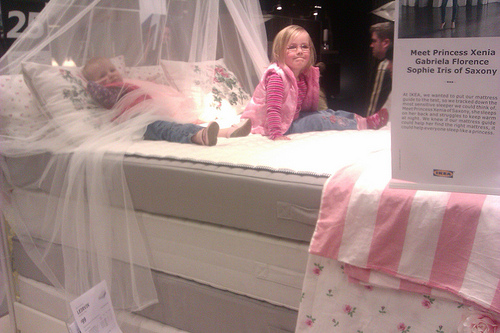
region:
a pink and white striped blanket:
[323, 168, 493, 303]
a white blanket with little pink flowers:
[300, 249, 420, 329]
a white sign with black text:
[383, 25, 497, 187]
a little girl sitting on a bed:
[250, 29, 385, 153]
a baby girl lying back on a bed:
[65, 39, 240, 155]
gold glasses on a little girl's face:
[281, 36, 313, 59]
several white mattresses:
[142, 174, 244, 306]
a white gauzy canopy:
[21, 13, 120, 274]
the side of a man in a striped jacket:
[354, 24, 393, 119]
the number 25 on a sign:
[5, 4, 45, 43]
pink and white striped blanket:
[322, 175, 495, 308]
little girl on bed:
[255, 28, 380, 135]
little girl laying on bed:
[83, 52, 243, 144]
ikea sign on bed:
[378, 4, 491, 191]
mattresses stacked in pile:
[169, 160, 242, 330]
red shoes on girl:
[363, 105, 386, 130]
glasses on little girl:
[281, 40, 311, 52]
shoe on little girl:
[197, 119, 222, 144]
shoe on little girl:
[224, 120, 256, 135]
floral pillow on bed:
[191, 52, 249, 113]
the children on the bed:
[81, 22, 388, 138]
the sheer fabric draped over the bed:
[8, 0, 265, 271]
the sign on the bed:
[392, 33, 499, 185]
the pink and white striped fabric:
[319, 177, 498, 291]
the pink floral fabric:
[299, 275, 425, 331]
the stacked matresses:
[128, 147, 230, 329]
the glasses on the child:
[284, 40, 309, 51]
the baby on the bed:
[81, 55, 253, 143]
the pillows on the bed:
[7, 45, 254, 125]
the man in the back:
[356, 17, 391, 111]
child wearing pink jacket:
[254, 22, 358, 123]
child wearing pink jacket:
[214, 15, 345, 160]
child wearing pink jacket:
[258, 48, 376, 175]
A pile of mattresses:
[18, 140, 238, 331]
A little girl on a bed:
[250, 15, 382, 154]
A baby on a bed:
[62, 37, 244, 171]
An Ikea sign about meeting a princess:
[385, 11, 499, 200]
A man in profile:
[356, 12, 405, 130]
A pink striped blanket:
[322, 137, 499, 314]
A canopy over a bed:
[14, 2, 259, 313]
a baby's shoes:
[191, 113, 260, 165]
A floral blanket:
[275, 257, 482, 331]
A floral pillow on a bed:
[156, 37, 256, 142]